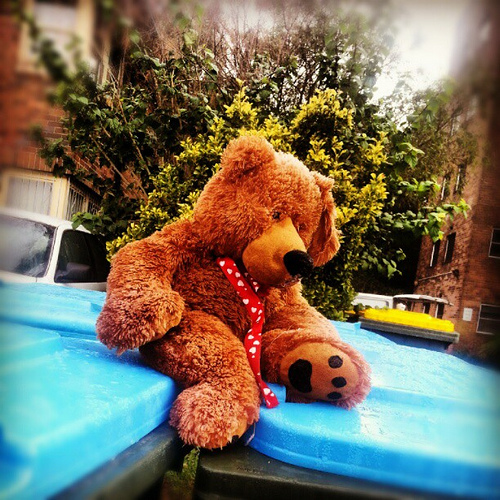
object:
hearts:
[235, 272, 240, 278]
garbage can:
[358, 307, 460, 352]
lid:
[364, 307, 455, 333]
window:
[54, 229, 111, 283]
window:
[0, 215, 53, 277]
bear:
[95, 133, 372, 451]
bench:
[240, 319, 500, 500]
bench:
[0, 279, 176, 500]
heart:
[219, 261, 225, 267]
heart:
[227, 268, 233, 274]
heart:
[263, 387, 271, 395]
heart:
[253, 340, 261, 345]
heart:
[248, 335, 254, 340]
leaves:
[16, 0, 477, 324]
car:
[0, 206, 108, 293]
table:
[385, 368, 476, 433]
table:
[0, 362, 89, 427]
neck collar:
[216, 256, 281, 410]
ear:
[219, 134, 275, 182]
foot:
[168, 382, 256, 452]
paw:
[114, 330, 162, 357]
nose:
[283, 250, 313, 278]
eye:
[273, 211, 281, 219]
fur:
[95, 132, 371, 450]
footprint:
[280, 342, 359, 402]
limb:
[95, 213, 196, 358]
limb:
[139, 309, 263, 450]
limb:
[261, 327, 372, 411]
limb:
[262, 280, 340, 339]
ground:
[4, 273, 97, 361]